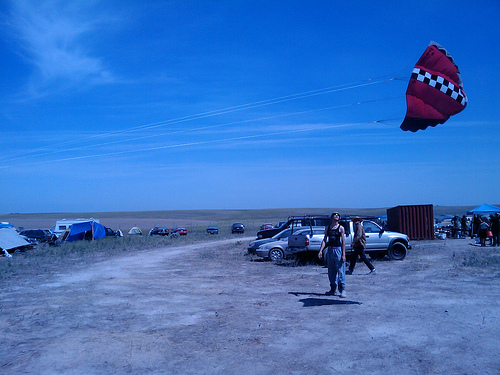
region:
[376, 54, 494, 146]
the parachute is purple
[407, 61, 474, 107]
the parachute is checked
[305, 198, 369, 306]
she is looking up in the sky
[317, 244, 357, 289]
the pants are green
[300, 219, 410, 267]
the car is silver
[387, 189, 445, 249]
the container is mettalic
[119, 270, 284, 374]
the ground is dry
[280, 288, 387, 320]
shadow is on the ground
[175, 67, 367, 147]
strings are attached to the parachute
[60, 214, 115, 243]
the tent is blue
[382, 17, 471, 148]
large kite in the air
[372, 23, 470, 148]
red, black, and white kite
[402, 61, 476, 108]
black and white checker pattern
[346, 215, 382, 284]
person walking on the dirt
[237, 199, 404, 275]
row of parked cars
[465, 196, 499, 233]
blue tent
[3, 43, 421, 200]
thin strings attached to the kite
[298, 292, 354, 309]
shadow on the ground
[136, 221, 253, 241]
cars parked on the grass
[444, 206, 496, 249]
crowd of people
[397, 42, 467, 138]
A kite being flown in the sky.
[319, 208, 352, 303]
An adult male standing alone.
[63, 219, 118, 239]
A blue tent set up on the ground.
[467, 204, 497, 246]
People gathered at a gazebo covering.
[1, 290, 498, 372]
A large patch of barren ground.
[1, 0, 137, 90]
A lone, sparse cloud.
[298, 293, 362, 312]
A shadow on the ground.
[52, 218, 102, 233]
A white camper parked behind a tent.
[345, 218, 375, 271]
A person walking by a silver truck.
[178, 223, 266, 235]
A row of cars parked together.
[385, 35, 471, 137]
The red kite in the air.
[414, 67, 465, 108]
The black and white checkered design on the kite.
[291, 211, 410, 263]
The gray truck parked.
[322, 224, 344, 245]
The black tank top the guy is wearing.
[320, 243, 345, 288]
The blue pants the guy is wearing.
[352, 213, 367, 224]
The beige hat the man is wearing next to the gray truck.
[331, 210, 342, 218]
The hat the guy in the black tank top is wearing.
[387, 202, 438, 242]
The brown metal storage box.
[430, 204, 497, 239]
The people on the right.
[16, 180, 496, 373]
The area the cars are parked.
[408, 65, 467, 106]
Strip of black and white checkers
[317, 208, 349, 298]
Person looking up at the sky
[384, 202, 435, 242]
Rusted metal dumpster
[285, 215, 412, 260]
Two door silver pickup truck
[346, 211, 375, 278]
Man with cowboy hat walking on the dirt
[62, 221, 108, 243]
Blue open tent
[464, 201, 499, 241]
Blue roof collapsible canopy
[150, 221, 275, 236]
Cars parked in the grass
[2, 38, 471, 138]
Burgundy parachute in the sky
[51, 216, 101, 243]
White camper